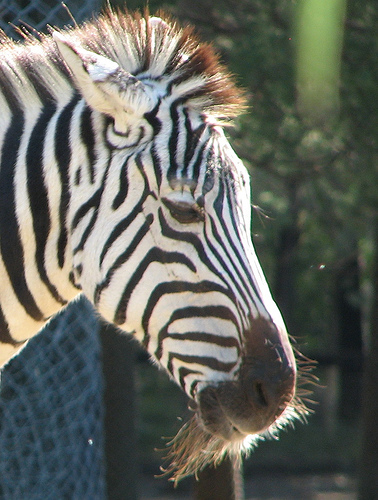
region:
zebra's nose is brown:
[172, 307, 328, 478]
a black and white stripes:
[69, 155, 283, 428]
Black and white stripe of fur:
[174, 354, 208, 395]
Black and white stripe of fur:
[201, 341, 244, 381]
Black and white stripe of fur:
[149, 331, 178, 363]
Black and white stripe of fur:
[167, 303, 209, 346]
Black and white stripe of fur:
[191, 272, 242, 322]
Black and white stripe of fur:
[224, 253, 271, 319]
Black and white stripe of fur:
[95, 216, 180, 288]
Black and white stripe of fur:
[157, 136, 218, 186]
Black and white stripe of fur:
[27, 143, 109, 191]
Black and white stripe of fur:
[23, 217, 110, 281]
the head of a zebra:
[6, 6, 310, 476]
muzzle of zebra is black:
[177, 312, 304, 450]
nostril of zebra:
[241, 368, 278, 413]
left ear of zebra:
[36, 28, 161, 129]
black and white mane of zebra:
[0, 13, 237, 122]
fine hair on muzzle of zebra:
[151, 330, 333, 484]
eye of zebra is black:
[154, 194, 208, 235]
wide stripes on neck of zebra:
[1, 92, 75, 342]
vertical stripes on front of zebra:
[199, 154, 270, 322]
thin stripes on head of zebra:
[90, 226, 232, 383]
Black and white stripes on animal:
[163, 342, 216, 387]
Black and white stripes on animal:
[192, 327, 240, 351]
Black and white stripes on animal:
[219, 299, 287, 356]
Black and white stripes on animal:
[140, 290, 201, 338]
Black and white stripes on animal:
[208, 273, 270, 319]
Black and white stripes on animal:
[121, 260, 182, 300]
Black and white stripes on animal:
[192, 246, 278, 292]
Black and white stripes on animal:
[82, 130, 153, 236]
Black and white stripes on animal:
[34, 208, 92, 255]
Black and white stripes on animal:
[29, 111, 134, 180]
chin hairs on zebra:
[153, 407, 229, 485]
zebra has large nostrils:
[246, 373, 275, 409]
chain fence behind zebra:
[19, 376, 94, 484]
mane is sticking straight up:
[97, 10, 246, 121]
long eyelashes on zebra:
[248, 200, 276, 233]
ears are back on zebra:
[49, 29, 181, 119]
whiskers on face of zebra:
[154, 343, 323, 485]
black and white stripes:
[3, 133, 84, 290]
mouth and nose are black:
[189, 340, 296, 444]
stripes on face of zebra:
[212, 159, 271, 333]